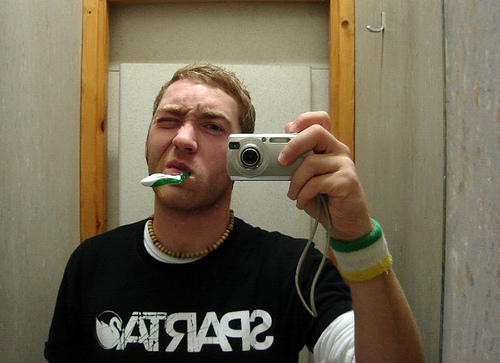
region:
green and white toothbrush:
[131, 150, 208, 197]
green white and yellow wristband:
[318, 227, 416, 285]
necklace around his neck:
[141, 202, 258, 276]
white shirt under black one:
[112, 213, 202, 288]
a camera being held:
[225, 117, 317, 187]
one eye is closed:
[152, 98, 232, 144]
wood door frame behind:
[27, 50, 162, 197]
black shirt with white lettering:
[78, 298, 164, 340]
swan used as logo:
[88, 295, 119, 350]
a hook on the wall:
[365, 5, 396, 52]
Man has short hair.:
[161, 55, 256, 108]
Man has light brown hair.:
[149, 33, 255, 130]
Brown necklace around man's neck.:
[141, 221, 234, 273]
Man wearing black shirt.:
[92, 261, 299, 352]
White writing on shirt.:
[108, 295, 284, 353]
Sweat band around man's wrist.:
[331, 215, 401, 298]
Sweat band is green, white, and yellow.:
[302, 219, 413, 283]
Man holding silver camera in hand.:
[219, 107, 332, 217]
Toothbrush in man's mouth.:
[131, 150, 208, 212]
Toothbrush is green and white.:
[126, 154, 206, 209]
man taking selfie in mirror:
[121, 116, 128, 131]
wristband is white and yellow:
[324, 225, 371, 277]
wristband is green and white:
[338, 240, 361, 271]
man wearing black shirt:
[268, 264, 273, 273]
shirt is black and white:
[153, 295, 174, 310]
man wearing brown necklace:
[183, 237, 238, 298]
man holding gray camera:
[255, 149, 277, 187]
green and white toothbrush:
[148, 163, 206, 218]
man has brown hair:
[237, 87, 254, 109]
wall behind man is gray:
[38, 145, 75, 215]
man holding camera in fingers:
[53, 64, 422, 361]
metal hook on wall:
[366, 10, 389, 34]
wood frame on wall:
[329, 4, 359, 144]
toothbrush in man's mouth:
[141, 160, 193, 186]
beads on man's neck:
[145, 208, 235, 258]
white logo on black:
[92, 305, 277, 355]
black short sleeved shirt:
[45, 214, 349, 361]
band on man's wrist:
[328, 223, 393, 280]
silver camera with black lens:
[224, 132, 310, 179]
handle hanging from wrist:
[290, 191, 332, 315]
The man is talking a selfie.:
[168, 95, 346, 211]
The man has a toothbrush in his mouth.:
[124, 143, 245, 219]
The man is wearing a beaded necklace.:
[127, 211, 244, 267]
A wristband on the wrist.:
[320, 220, 385, 286]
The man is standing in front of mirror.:
[85, 41, 372, 297]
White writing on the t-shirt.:
[64, 285, 261, 361]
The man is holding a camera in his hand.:
[213, 125, 365, 197]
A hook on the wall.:
[358, 8, 403, 47]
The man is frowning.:
[146, 82, 243, 234]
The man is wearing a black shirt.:
[58, 221, 322, 354]